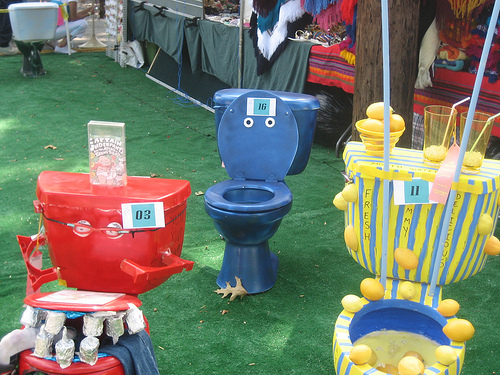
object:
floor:
[173, 302, 328, 374]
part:
[165, 88, 213, 108]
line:
[165, 4, 213, 109]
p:
[216, 241, 279, 294]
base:
[208, 202, 281, 294]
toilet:
[204, 88, 320, 294]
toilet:
[333, 141, 500, 375]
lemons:
[355, 101, 406, 156]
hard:
[38, 170, 190, 200]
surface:
[52, 197, 126, 262]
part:
[0, 171, 194, 375]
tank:
[16, 171, 194, 295]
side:
[159, 178, 192, 255]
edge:
[235, 276, 243, 286]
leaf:
[207, 273, 244, 308]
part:
[97, 329, 161, 375]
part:
[50, 0, 88, 54]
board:
[105, 0, 127, 67]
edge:
[12, 39, 48, 77]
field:
[52, 64, 126, 117]